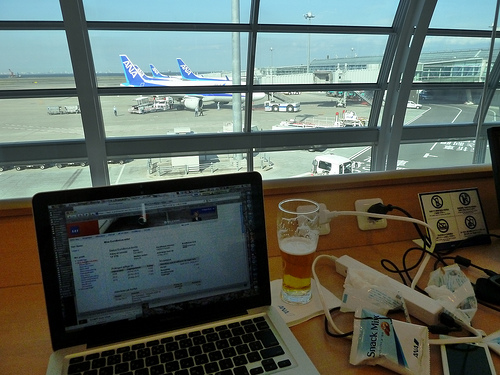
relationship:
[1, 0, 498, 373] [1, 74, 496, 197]
control tower near tarmac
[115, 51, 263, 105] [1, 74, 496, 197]
plane on tarmac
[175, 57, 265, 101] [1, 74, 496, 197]
plane on tarmac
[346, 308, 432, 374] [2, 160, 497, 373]
snack pack on desk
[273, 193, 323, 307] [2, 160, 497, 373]
glass on desk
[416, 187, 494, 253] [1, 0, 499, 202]
sign underneath window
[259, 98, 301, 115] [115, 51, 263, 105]
loading vehicle next to plane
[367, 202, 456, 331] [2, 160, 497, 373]
electrical cord on desk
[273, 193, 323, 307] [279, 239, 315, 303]
glass of beer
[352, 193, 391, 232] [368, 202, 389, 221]
outlet has plug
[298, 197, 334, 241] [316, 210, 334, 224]
outlet has plug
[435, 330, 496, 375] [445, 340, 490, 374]
cell phone has touch screen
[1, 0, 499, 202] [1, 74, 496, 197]
window looks out onto tarmac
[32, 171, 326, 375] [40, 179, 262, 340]
computer has screen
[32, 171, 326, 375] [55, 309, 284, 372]
computer has keyboard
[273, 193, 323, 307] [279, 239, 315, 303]
glass has beer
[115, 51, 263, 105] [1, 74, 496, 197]
plane parked on tarmac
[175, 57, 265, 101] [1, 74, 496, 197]
plane parked on tarmac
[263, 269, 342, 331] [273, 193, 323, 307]
napkin under glass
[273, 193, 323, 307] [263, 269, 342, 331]
glass on a napkin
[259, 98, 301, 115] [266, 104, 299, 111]
loading vehicle has stripe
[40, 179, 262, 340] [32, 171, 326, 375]
screen on computer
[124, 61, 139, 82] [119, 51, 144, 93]
logo on tail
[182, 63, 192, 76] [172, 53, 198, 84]
logo on tail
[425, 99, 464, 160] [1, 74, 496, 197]
line on tarmac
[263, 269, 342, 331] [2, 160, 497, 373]
napkin on desk